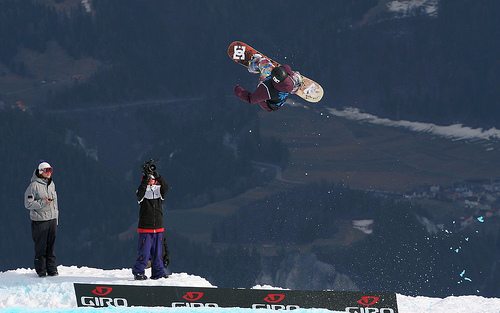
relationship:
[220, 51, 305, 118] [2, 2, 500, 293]
man in air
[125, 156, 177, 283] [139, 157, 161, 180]
man holding camera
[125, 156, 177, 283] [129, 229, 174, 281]
man wearing pants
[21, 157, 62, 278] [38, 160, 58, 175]
man wearing goggles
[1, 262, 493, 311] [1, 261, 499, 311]
snow on ground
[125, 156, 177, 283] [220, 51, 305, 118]
man recording man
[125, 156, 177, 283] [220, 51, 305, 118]
man watching man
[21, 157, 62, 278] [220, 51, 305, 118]
man watching man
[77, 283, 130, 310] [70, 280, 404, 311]
giro on banner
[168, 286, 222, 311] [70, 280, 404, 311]
giro on banner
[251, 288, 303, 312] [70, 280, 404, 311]
giro on banner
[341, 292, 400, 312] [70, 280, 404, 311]
giro on banner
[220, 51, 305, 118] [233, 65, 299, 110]
man wearing jacket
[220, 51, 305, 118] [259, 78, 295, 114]
man wearing vest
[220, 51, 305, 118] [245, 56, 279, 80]
man wearing pants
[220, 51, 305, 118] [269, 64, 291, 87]
man wearing helmet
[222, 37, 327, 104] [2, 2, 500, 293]
snowboard in air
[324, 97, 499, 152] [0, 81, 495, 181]
snow on hill